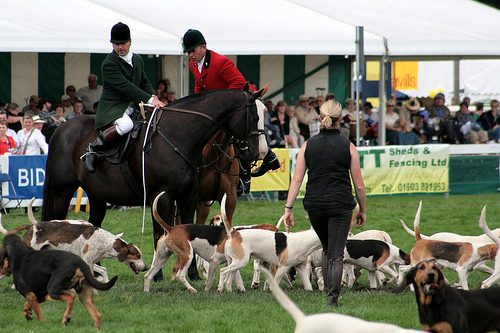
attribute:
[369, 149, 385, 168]
letter — green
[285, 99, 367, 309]
woman — walking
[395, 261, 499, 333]
dog — here, black, hunting, ready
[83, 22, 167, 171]
rider — here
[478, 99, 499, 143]
spectator — watching, here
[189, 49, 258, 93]
coat — red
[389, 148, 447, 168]
advertisement — green, here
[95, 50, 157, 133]
coat — green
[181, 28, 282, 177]
rider — mounting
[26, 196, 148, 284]
beagle — white